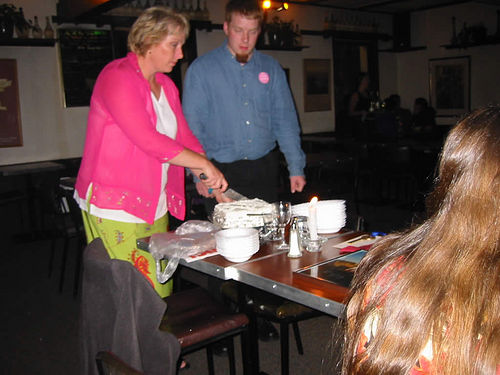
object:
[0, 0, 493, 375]
house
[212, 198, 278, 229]
cake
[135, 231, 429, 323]
table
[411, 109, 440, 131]
jacket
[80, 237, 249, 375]
chair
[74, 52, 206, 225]
jacket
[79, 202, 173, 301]
pant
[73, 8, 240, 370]
people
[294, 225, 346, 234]
plate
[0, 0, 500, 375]
celebration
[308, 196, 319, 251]
candle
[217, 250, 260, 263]
bowl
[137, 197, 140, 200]
button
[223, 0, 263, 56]
head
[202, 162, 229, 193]
hand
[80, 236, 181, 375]
coat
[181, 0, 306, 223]
man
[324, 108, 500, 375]
waitress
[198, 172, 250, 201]
knife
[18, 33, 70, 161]
wall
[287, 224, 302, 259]
salt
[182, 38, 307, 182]
shirt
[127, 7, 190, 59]
hair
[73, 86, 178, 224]
shirt